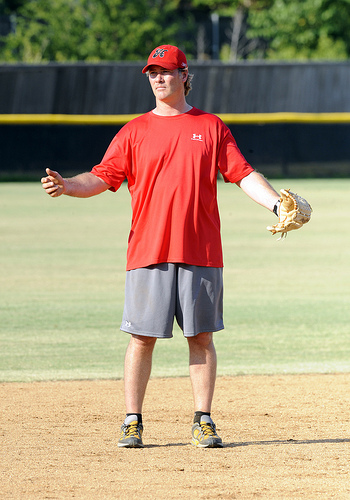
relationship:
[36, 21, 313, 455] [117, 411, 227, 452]
man in shoes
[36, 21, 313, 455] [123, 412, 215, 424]
man in socks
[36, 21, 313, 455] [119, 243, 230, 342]
man in shorts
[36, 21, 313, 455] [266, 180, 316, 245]
man in glove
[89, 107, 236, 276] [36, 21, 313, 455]
shirt on man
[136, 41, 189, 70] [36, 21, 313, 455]
cap on man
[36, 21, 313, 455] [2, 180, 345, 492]
man on field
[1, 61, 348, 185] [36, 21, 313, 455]
wall behind man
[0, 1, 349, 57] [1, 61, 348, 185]
trees behind wall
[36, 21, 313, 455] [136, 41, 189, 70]
man in cap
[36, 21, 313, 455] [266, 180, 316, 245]
man holding glove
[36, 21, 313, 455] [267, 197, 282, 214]
man wearing watch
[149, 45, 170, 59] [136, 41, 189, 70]
logo on cap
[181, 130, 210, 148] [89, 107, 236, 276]
logo on shirt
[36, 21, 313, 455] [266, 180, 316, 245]
man with glove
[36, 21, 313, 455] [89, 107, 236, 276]
man in shirt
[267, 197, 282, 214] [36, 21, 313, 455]
watch on man